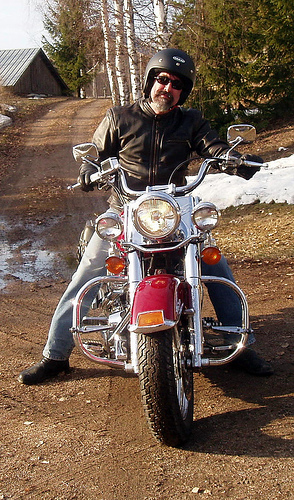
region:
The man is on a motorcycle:
[34, 35, 273, 446]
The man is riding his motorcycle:
[51, 42, 265, 464]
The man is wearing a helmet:
[133, 38, 196, 112]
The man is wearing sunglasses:
[127, 32, 202, 124]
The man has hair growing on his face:
[132, 42, 196, 126]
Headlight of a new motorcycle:
[132, 193, 175, 235]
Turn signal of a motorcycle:
[198, 244, 219, 263]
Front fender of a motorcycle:
[133, 278, 175, 328]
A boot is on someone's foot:
[12, 346, 71, 392]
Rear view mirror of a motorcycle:
[226, 124, 254, 144]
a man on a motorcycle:
[17, 47, 272, 443]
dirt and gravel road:
[34, 403, 117, 480]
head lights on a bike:
[89, 198, 224, 250]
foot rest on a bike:
[189, 271, 254, 372]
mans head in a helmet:
[139, 48, 201, 102]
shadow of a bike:
[202, 309, 293, 471]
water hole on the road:
[1, 203, 74, 290]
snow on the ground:
[219, 169, 293, 216]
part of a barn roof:
[1, 40, 75, 102]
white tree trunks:
[109, 7, 134, 87]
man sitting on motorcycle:
[14, 56, 278, 461]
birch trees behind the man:
[88, 3, 140, 102]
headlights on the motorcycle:
[93, 191, 222, 243]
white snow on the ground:
[214, 175, 284, 203]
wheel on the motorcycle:
[121, 327, 210, 455]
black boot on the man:
[13, 350, 76, 401]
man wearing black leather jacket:
[95, 50, 266, 186]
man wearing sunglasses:
[128, 46, 201, 116]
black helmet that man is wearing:
[131, 40, 211, 70]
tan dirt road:
[26, 415, 107, 472]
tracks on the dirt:
[94, 382, 137, 431]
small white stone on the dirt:
[184, 486, 203, 492]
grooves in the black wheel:
[138, 359, 165, 382]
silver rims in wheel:
[175, 346, 195, 392]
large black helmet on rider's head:
[139, 49, 209, 76]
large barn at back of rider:
[17, 47, 75, 100]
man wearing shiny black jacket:
[105, 105, 208, 170]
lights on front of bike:
[194, 246, 226, 270]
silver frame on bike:
[98, 198, 221, 326]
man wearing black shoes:
[8, 359, 79, 385]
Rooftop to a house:
[2, 26, 104, 113]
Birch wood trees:
[83, 0, 208, 131]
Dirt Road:
[0, 74, 143, 197]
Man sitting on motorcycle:
[48, 38, 208, 227]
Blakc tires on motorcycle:
[124, 305, 229, 457]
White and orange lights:
[75, 180, 231, 337]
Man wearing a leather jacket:
[54, 21, 270, 202]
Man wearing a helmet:
[88, 36, 235, 178]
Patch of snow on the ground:
[105, 128, 289, 245]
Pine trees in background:
[156, 0, 290, 142]